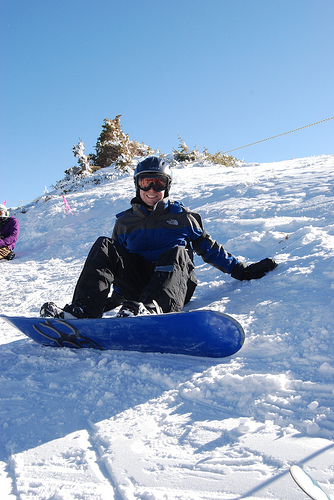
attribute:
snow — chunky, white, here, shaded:
[254, 217, 291, 237]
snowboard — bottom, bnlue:
[49, 323, 200, 354]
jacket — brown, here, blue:
[110, 213, 144, 229]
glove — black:
[242, 262, 276, 276]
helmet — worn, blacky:
[134, 160, 159, 172]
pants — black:
[88, 254, 193, 285]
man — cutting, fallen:
[65, 130, 210, 284]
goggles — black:
[139, 180, 170, 190]